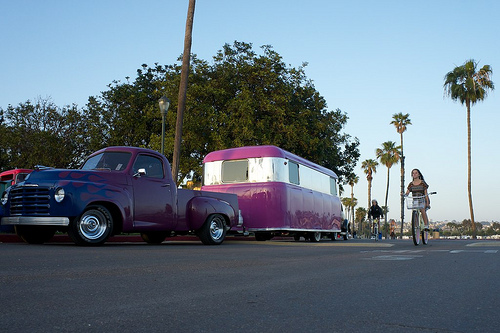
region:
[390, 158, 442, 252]
woman on bicycle riding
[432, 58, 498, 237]
palm tree on street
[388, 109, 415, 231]
palm tree on street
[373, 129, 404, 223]
palm tree on street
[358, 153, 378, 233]
palm tree on street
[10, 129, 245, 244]
old fashioned blue truck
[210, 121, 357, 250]
purple trailer on back of truck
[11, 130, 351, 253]
blue truck pulling purple trailer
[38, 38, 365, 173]
green trees behind truck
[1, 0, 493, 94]
pretty blue sky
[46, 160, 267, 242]
brown classic truck pulling trailer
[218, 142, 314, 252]
trailer is purple and white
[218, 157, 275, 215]
front window of trailer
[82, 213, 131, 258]
chrome front rim on truck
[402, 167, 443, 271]
female riding on bike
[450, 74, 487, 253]
tall thin palm tree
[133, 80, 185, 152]
lamp post behind truck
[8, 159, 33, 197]
cab of red truck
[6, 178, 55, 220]
front grill of brown truck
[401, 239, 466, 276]
white lines on street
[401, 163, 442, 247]
A woman riding a bicycle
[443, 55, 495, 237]
A tall palm tree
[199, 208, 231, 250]
A black round tire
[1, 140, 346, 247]
A truck pulling a trailer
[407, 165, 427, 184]
Woman has dark hair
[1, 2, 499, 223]
The sky is clear and blue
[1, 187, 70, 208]
Two headlights on a truck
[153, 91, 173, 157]
A tall street lamp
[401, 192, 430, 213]
A basket on a bicycle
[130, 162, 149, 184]
A side mirror on a truck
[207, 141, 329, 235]
red trailer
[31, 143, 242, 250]
truck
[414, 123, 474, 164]
white clouds in blue sky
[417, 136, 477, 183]
white clouds in blue sky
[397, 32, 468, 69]
white clouds in blue sky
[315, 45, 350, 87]
white clouds in blue sky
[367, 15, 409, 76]
white clouds in blue sky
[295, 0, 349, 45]
white clouds in blue sky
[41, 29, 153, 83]
white clouds in blue sky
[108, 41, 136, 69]
white clouds in blue sky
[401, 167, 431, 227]
girl in brown shirt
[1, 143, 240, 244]
purple classic truck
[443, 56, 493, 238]
tall palm tree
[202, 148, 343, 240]
pink and white classic trailer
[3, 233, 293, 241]
red part of roadside curb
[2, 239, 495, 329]
paved street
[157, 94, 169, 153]
metal street lamp that is dark green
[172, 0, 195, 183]
tall tree trunk behind purple truck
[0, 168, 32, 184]
top of red vehicle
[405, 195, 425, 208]
wire bike basket